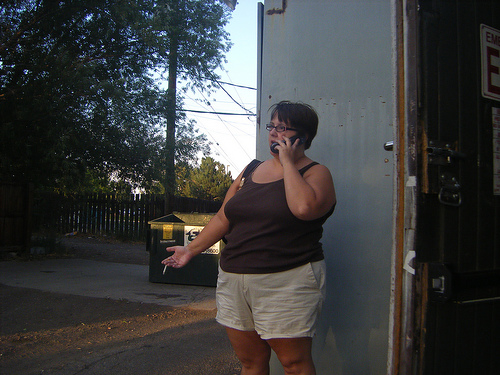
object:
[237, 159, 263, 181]
purse strap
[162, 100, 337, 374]
woman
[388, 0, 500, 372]
door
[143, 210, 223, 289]
dumpster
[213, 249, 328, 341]
shorts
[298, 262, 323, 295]
pocket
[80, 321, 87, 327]
leaves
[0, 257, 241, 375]
ground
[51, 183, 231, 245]
fence